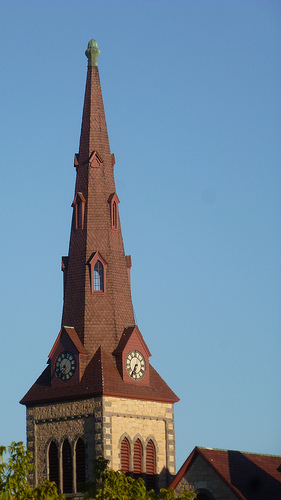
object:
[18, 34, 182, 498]
clock tower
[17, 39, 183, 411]
roof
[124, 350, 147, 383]
clock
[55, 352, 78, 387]
clock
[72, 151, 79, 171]
part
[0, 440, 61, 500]
plant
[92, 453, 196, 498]
leavesa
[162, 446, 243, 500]
edge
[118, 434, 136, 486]
window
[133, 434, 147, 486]
window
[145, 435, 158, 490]
vent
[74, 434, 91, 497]
red vent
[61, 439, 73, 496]
shutter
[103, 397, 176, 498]
wall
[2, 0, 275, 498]
picture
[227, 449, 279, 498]
part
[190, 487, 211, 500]
part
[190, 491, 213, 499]
window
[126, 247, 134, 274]
edge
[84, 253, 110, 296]
window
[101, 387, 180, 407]
edge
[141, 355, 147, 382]
edge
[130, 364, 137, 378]
part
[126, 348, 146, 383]
roman numerals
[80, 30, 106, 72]
top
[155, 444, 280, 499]
building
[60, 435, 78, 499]
red vent